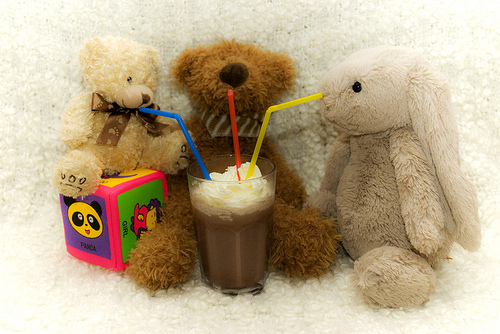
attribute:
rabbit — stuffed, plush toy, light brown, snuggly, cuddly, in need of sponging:
[300, 43, 485, 315]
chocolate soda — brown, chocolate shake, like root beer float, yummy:
[187, 142, 278, 298]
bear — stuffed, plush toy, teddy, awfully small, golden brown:
[48, 32, 200, 202]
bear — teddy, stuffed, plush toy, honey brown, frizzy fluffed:
[121, 28, 346, 304]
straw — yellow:
[243, 93, 321, 178]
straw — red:
[225, 87, 242, 183]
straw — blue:
[136, 103, 215, 180]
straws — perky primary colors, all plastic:
[136, 87, 324, 183]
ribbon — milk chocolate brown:
[90, 93, 169, 151]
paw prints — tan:
[95, 102, 154, 141]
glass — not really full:
[187, 154, 276, 291]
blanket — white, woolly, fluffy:
[1, 1, 499, 333]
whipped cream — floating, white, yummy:
[192, 159, 274, 212]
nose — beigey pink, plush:
[315, 86, 333, 108]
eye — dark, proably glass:
[126, 74, 133, 84]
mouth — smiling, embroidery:
[119, 98, 147, 113]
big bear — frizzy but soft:
[119, 40, 344, 298]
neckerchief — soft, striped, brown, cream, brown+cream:
[191, 104, 275, 144]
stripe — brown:
[200, 107, 214, 124]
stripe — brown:
[242, 115, 255, 137]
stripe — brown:
[216, 112, 236, 136]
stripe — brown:
[207, 109, 225, 135]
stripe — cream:
[239, 117, 251, 136]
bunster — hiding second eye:
[303, 38, 486, 316]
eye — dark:
[349, 77, 365, 97]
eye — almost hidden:
[219, 54, 229, 62]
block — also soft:
[63, 165, 169, 277]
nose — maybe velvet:
[217, 60, 250, 90]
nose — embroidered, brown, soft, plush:
[138, 90, 154, 108]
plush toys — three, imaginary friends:
[46, 31, 488, 321]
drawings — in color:
[69, 171, 161, 249]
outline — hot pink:
[63, 166, 166, 270]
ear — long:
[407, 62, 483, 257]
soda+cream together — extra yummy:
[193, 159, 269, 289]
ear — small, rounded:
[73, 29, 108, 76]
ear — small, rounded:
[144, 47, 165, 76]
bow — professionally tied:
[86, 88, 172, 154]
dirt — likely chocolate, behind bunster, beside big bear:
[270, 108, 332, 157]